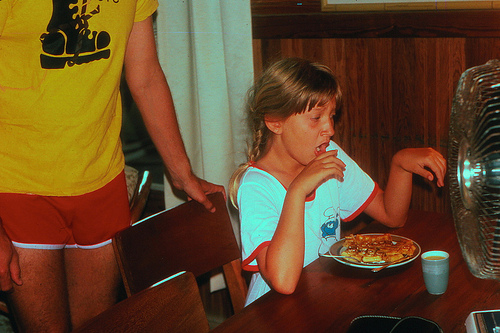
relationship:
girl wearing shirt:
[228, 56, 448, 309] [319, 204, 339, 244]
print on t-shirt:
[320, 207, 341, 235] [236, 140, 381, 309]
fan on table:
[444, 58, 499, 278] [250, 214, 477, 330]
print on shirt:
[37, 0, 111, 70] [3, 7, 162, 194]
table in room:
[250, 214, 477, 330] [1, 1, 500, 333]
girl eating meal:
[228, 56, 448, 309] [338, 233, 419, 265]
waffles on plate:
[344, 231, 415, 259] [332, 227, 422, 276]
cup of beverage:
[418, 249, 458, 297] [423, 255, 446, 260]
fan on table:
[435, 61, 484, 276] [219, 212, 478, 322]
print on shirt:
[320, 207, 341, 235] [233, 143, 370, 281]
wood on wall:
[272, 14, 470, 153] [258, 2, 484, 215]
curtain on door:
[153, 2, 273, 299] [115, 81, 165, 200]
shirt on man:
[3, 7, 162, 194] [1, 0, 229, 325]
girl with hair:
[228, 56, 448, 309] [225, 54, 344, 212]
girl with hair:
[228, 59, 338, 205] [265, 70, 295, 92]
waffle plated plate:
[347, 232, 400, 258] [332, 228, 416, 269]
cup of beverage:
[418, 250, 448, 293] [430, 251, 440, 261]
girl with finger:
[228, 56, 448, 309] [314, 136, 327, 155]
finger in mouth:
[314, 136, 327, 155] [314, 141, 333, 157]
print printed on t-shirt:
[320, 207, 341, 235] [236, 140, 381, 309]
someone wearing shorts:
[1, 0, 229, 330] [0, 169, 133, 250]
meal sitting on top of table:
[338, 230, 418, 265] [207, 206, 484, 329]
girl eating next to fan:
[228, 56, 448, 309] [444, 58, 499, 278]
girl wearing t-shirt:
[228, 56, 448, 309] [236, 140, 381, 309]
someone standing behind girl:
[1, 0, 229, 333] [228, 56, 448, 309]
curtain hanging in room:
[153, 0, 262, 296] [1, 1, 484, 330]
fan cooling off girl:
[444, 58, 499, 278] [228, 56, 448, 309]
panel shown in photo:
[250, 7, 482, 239] [1, 1, 483, 329]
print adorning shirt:
[37, 0, 111, 70] [0, 0, 163, 198]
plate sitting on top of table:
[330, 231, 421, 270] [207, 206, 484, 329]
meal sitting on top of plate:
[338, 233, 419, 265] [330, 231, 421, 270]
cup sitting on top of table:
[418, 250, 448, 293] [207, 206, 484, 329]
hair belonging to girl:
[225, 54, 344, 212] [228, 56, 448, 309]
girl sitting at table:
[228, 56, 448, 309] [207, 206, 484, 329]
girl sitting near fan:
[228, 56, 448, 309] [444, 58, 499, 278]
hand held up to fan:
[390, 142, 447, 188] [444, 58, 499, 278]